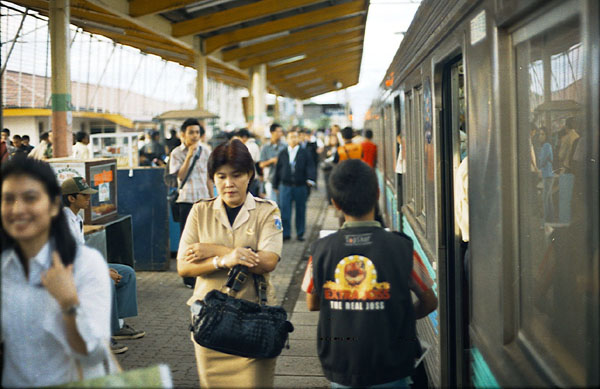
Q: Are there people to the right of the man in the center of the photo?
A: Yes, there is a person to the right of the man.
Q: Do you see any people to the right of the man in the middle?
A: Yes, there is a person to the right of the man.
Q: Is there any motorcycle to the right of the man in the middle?
A: No, there is a person to the right of the man.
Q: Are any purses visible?
A: Yes, there is a purse.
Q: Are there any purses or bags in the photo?
A: Yes, there is a purse.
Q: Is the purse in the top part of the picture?
A: No, the purse is in the bottom of the image.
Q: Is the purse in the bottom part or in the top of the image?
A: The purse is in the bottom of the image.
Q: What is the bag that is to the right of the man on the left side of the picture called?
A: The bag is a purse.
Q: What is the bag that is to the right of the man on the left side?
A: The bag is a purse.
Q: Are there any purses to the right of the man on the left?
A: Yes, there is a purse to the right of the man.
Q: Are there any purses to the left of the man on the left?
A: No, the purse is to the right of the man.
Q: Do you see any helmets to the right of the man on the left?
A: No, there is a purse to the right of the man.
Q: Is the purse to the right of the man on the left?
A: Yes, the purse is to the right of the man.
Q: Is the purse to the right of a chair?
A: No, the purse is to the right of the man.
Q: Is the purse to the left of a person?
A: No, the purse is to the right of a person.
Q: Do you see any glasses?
A: No, there are no glasses.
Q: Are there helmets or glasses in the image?
A: No, there are no glasses or helmets.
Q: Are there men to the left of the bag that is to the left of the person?
A: Yes, there is a man to the left of the purse.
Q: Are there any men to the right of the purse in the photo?
A: No, the man is to the left of the purse.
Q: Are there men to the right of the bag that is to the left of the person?
A: No, the man is to the left of the purse.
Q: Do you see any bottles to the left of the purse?
A: No, there is a man to the left of the purse.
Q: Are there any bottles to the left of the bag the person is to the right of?
A: No, there is a man to the left of the purse.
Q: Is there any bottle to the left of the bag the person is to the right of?
A: No, there is a man to the left of the purse.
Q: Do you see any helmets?
A: No, there are no helmets.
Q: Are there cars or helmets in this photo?
A: No, there are no helmets or cars.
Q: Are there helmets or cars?
A: No, there are no helmets or cars.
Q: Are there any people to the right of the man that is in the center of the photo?
A: Yes, there is a person to the right of the man.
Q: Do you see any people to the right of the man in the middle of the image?
A: Yes, there is a person to the right of the man.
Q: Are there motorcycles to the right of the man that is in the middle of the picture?
A: No, there is a person to the right of the man.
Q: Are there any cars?
A: No, there are no cars.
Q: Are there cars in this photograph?
A: No, there are no cars.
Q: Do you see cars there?
A: No, there are no cars.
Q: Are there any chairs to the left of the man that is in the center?
A: No, there is a person to the left of the man.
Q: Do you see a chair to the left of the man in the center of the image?
A: No, there is a person to the left of the man.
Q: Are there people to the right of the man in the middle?
A: Yes, there is a person to the right of the man.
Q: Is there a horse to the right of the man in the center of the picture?
A: No, there is a person to the right of the man.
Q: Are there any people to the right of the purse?
A: Yes, there is a person to the right of the purse.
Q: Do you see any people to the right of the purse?
A: Yes, there is a person to the right of the purse.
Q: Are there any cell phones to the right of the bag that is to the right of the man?
A: No, there is a person to the right of the purse.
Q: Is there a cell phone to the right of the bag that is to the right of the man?
A: No, there is a person to the right of the purse.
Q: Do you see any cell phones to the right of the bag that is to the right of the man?
A: No, there is a person to the right of the purse.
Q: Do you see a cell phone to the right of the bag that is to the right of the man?
A: No, there is a person to the right of the purse.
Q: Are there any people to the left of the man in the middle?
A: Yes, there is a person to the left of the man.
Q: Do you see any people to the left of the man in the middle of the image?
A: Yes, there is a person to the left of the man.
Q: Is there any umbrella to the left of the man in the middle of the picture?
A: No, there is a person to the left of the man.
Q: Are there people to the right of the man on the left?
A: Yes, there is a person to the right of the man.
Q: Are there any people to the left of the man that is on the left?
A: No, the person is to the right of the man.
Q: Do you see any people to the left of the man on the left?
A: No, the person is to the right of the man.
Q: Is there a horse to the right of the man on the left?
A: No, there is a person to the right of the man.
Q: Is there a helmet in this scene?
A: No, there are no helmets.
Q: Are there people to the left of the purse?
A: Yes, there is a person to the left of the purse.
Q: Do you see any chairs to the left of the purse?
A: No, there is a person to the left of the purse.